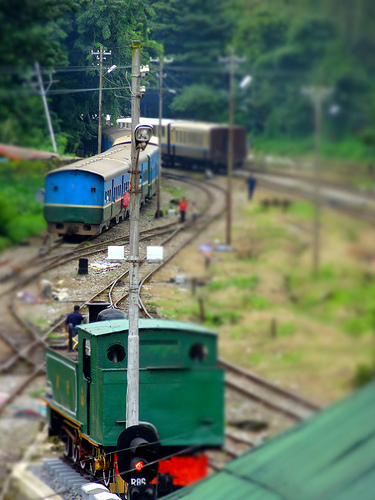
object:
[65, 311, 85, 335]
shirt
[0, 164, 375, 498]
railway crossway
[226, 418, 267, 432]
trees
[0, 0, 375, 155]
green trees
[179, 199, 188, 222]
figurine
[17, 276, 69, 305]
trash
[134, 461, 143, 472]
light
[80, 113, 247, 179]
train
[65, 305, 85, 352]
person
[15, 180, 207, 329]
gravel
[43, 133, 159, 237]
train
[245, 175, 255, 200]
person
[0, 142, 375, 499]
ground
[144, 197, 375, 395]
grass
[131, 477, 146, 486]
plate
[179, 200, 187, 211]
red shirt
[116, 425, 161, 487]
plates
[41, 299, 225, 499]
cab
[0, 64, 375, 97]
wires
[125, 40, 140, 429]
pole